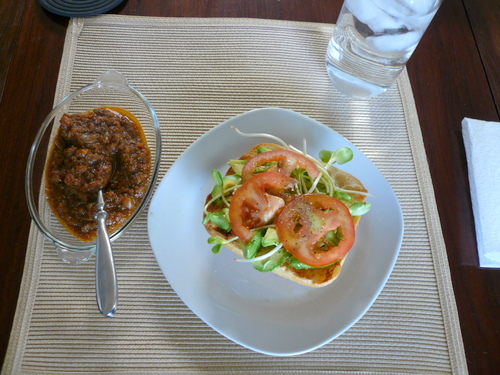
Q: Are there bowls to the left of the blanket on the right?
A: Yes, there is a bowl to the left of the blanket.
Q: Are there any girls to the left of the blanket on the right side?
A: No, there is a bowl to the left of the blanket.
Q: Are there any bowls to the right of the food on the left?
A: Yes, there is a bowl to the right of the food.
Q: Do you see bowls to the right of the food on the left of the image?
A: Yes, there is a bowl to the right of the food.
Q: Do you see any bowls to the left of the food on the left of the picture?
A: No, the bowl is to the right of the food.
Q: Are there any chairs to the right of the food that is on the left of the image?
A: No, there is a bowl to the right of the food.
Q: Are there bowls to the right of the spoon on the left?
A: Yes, there is a bowl to the right of the spoon.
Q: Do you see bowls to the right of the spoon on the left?
A: Yes, there is a bowl to the right of the spoon.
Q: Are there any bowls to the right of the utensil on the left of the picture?
A: Yes, there is a bowl to the right of the spoon.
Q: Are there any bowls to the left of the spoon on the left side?
A: No, the bowl is to the right of the spoon.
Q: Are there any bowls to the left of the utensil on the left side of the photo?
A: No, the bowl is to the right of the spoon.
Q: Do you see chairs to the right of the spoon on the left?
A: No, there is a bowl to the right of the spoon.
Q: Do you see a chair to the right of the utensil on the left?
A: No, there is a bowl to the right of the spoon.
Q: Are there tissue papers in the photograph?
A: No, there are no tissue papers.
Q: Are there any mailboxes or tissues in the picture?
A: No, there are no tissues or mailboxes.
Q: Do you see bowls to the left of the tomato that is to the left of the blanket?
A: Yes, there is a bowl to the left of the tomato.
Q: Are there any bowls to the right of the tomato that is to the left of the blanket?
A: No, the bowl is to the left of the tomato.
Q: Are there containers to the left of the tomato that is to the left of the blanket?
A: No, there is a bowl to the left of the tomato.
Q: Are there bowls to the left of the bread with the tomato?
A: Yes, there is a bowl to the left of the bread.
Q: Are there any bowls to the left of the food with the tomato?
A: Yes, there is a bowl to the left of the bread.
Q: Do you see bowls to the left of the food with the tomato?
A: Yes, there is a bowl to the left of the bread.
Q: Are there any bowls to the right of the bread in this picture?
A: No, the bowl is to the left of the bread.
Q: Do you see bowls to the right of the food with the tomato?
A: No, the bowl is to the left of the bread.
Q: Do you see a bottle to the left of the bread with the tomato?
A: No, there is a bowl to the left of the bread.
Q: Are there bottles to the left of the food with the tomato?
A: No, there is a bowl to the left of the bread.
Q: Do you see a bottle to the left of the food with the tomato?
A: No, there is a bowl to the left of the bread.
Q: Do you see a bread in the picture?
A: Yes, there is a bread.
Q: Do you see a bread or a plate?
A: Yes, there is a bread.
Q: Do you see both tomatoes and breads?
A: Yes, there are both a bread and a tomato.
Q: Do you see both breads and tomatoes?
A: Yes, there are both a bread and a tomato.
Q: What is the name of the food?
A: The food is a bread.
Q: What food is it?
A: The food is a bread.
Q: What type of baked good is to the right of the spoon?
A: The food is a bread.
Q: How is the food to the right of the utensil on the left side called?
A: The food is a bread.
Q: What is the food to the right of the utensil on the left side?
A: The food is a bread.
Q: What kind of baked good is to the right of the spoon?
A: The food is a bread.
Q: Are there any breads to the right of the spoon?
A: Yes, there is a bread to the right of the spoon.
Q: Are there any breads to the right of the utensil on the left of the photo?
A: Yes, there is a bread to the right of the spoon.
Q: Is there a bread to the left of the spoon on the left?
A: No, the bread is to the right of the spoon.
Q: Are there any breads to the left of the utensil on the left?
A: No, the bread is to the right of the spoon.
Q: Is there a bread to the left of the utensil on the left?
A: No, the bread is to the right of the spoon.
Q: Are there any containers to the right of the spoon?
A: No, there is a bread to the right of the spoon.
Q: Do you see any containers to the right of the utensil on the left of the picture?
A: No, there is a bread to the right of the spoon.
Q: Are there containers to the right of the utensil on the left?
A: No, there is a bread to the right of the spoon.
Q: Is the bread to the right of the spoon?
A: Yes, the bread is to the right of the spoon.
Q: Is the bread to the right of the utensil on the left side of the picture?
A: Yes, the bread is to the right of the spoon.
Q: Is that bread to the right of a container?
A: No, the bread is to the right of the spoon.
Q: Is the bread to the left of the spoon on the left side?
A: No, the bread is to the right of the spoon.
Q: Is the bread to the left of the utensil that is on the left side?
A: No, the bread is to the right of the spoon.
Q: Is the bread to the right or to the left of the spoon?
A: The bread is to the right of the spoon.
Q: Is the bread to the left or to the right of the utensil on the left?
A: The bread is to the right of the spoon.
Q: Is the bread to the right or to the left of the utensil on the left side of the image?
A: The bread is to the right of the spoon.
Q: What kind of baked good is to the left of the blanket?
A: The food is a bread.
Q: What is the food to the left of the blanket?
A: The food is a bread.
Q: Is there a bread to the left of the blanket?
A: Yes, there is a bread to the left of the blanket.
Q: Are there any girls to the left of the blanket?
A: No, there is a bread to the left of the blanket.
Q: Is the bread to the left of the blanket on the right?
A: Yes, the bread is to the left of the blanket.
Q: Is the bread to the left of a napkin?
A: No, the bread is to the left of the blanket.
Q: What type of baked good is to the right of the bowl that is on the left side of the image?
A: The food is a bread.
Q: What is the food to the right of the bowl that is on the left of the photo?
A: The food is a bread.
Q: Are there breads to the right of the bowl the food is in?
A: Yes, there is a bread to the right of the bowl.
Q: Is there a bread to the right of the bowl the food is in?
A: Yes, there is a bread to the right of the bowl.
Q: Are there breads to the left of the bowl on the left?
A: No, the bread is to the right of the bowl.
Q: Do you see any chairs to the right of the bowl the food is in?
A: No, there is a bread to the right of the bowl.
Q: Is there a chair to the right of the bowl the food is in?
A: No, there is a bread to the right of the bowl.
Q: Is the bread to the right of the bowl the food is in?
A: Yes, the bread is to the right of the bowl.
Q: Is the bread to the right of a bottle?
A: No, the bread is to the right of the bowl.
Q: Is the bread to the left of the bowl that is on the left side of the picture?
A: No, the bread is to the right of the bowl.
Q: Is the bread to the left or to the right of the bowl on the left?
A: The bread is to the right of the bowl.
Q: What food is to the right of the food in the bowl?
A: The food is a bread.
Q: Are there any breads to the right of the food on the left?
A: Yes, there is a bread to the right of the food.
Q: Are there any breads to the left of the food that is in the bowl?
A: No, the bread is to the right of the food.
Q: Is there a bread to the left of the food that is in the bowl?
A: No, the bread is to the right of the food.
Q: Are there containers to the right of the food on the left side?
A: No, there is a bread to the right of the food.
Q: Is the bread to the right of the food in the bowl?
A: Yes, the bread is to the right of the food.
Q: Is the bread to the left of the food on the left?
A: No, the bread is to the right of the food.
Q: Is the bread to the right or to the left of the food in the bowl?
A: The bread is to the right of the food.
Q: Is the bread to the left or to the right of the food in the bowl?
A: The bread is to the right of the food.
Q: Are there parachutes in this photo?
A: No, there are no parachutes.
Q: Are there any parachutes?
A: No, there are no parachutes.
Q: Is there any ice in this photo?
A: Yes, there is ice.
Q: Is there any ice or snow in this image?
A: Yes, there is ice.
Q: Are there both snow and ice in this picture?
A: No, there is ice but no snow.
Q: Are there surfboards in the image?
A: No, there are no surfboards.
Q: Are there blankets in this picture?
A: Yes, there is a blanket.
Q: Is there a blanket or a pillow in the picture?
A: Yes, there is a blanket.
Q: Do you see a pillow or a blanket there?
A: Yes, there is a blanket.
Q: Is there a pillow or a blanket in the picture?
A: Yes, there is a blanket.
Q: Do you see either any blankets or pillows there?
A: Yes, there is a blanket.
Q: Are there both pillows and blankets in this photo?
A: No, there is a blanket but no pillows.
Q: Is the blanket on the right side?
A: Yes, the blanket is on the right of the image.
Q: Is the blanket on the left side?
A: No, the blanket is on the right of the image.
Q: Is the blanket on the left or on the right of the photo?
A: The blanket is on the right of the image.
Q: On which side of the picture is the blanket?
A: The blanket is on the right of the image.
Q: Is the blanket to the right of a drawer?
A: No, the blanket is to the right of the vegetable.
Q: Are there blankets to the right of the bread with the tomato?
A: Yes, there is a blanket to the right of the bread.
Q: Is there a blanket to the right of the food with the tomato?
A: Yes, there is a blanket to the right of the bread.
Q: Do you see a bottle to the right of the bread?
A: No, there is a blanket to the right of the bread.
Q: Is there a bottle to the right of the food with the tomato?
A: No, there is a blanket to the right of the bread.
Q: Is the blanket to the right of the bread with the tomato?
A: Yes, the blanket is to the right of the bread.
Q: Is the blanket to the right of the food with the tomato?
A: Yes, the blanket is to the right of the bread.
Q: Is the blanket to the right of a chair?
A: No, the blanket is to the right of the bread.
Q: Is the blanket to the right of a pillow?
A: No, the blanket is to the right of the bowl.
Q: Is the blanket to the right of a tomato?
A: Yes, the blanket is to the right of a tomato.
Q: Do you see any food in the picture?
A: Yes, there is food.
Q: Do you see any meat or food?
A: Yes, there is food.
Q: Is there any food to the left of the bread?
A: Yes, there is food to the left of the bread.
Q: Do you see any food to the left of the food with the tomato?
A: Yes, there is food to the left of the bread.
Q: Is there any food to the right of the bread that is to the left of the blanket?
A: No, the food is to the left of the bread.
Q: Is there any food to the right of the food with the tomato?
A: No, the food is to the left of the bread.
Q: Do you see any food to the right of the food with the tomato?
A: No, the food is to the left of the bread.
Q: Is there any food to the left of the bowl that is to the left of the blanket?
A: Yes, there is food to the left of the bowl.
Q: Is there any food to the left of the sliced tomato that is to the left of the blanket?
A: Yes, there is food to the left of the tomato.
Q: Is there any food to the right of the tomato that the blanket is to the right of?
A: No, the food is to the left of the tomato.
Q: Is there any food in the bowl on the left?
A: Yes, there is food in the bowl.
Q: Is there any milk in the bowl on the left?
A: No, there is food in the bowl.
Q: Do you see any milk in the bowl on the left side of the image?
A: No, there is food in the bowl.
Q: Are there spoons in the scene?
A: Yes, there is a spoon.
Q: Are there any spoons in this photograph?
A: Yes, there is a spoon.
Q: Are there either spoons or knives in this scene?
A: Yes, there is a spoon.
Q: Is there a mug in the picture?
A: No, there are no mugs.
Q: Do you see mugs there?
A: No, there are no mugs.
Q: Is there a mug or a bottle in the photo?
A: No, there are no mugs or bottles.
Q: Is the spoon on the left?
A: Yes, the spoon is on the left of the image.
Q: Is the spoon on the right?
A: No, the spoon is on the left of the image.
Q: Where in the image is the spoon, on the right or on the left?
A: The spoon is on the left of the image.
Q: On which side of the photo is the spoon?
A: The spoon is on the left of the image.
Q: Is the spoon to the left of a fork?
A: No, the spoon is to the left of the vegetable.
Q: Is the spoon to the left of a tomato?
A: Yes, the spoon is to the left of a tomato.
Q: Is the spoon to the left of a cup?
A: No, the spoon is to the left of a tomato.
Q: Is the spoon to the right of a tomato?
A: No, the spoon is to the left of a tomato.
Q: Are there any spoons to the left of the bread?
A: Yes, there is a spoon to the left of the bread.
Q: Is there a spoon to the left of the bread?
A: Yes, there is a spoon to the left of the bread.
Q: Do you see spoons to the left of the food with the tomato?
A: Yes, there is a spoon to the left of the bread.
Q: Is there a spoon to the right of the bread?
A: No, the spoon is to the left of the bread.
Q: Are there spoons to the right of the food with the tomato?
A: No, the spoon is to the left of the bread.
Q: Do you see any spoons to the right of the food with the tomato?
A: No, the spoon is to the left of the bread.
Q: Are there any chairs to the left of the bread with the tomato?
A: No, there is a spoon to the left of the bread.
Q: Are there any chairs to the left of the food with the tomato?
A: No, there is a spoon to the left of the bread.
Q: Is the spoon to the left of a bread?
A: Yes, the spoon is to the left of a bread.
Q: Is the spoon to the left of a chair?
A: No, the spoon is to the left of a bread.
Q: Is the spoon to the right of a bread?
A: No, the spoon is to the left of a bread.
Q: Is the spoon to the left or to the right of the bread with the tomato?
A: The spoon is to the left of the bread.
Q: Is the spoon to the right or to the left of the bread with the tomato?
A: The spoon is to the left of the bread.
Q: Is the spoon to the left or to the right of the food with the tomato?
A: The spoon is to the left of the bread.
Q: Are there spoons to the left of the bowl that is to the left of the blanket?
A: Yes, there is a spoon to the left of the bowl.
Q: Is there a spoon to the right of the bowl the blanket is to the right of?
A: No, the spoon is to the left of the bowl.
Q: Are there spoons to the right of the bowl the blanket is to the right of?
A: No, the spoon is to the left of the bowl.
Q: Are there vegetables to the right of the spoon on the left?
A: Yes, there is a vegetable to the right of the spoon.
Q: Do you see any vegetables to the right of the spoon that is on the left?
A: Yes, there is a vegetable to the right of the spoon.